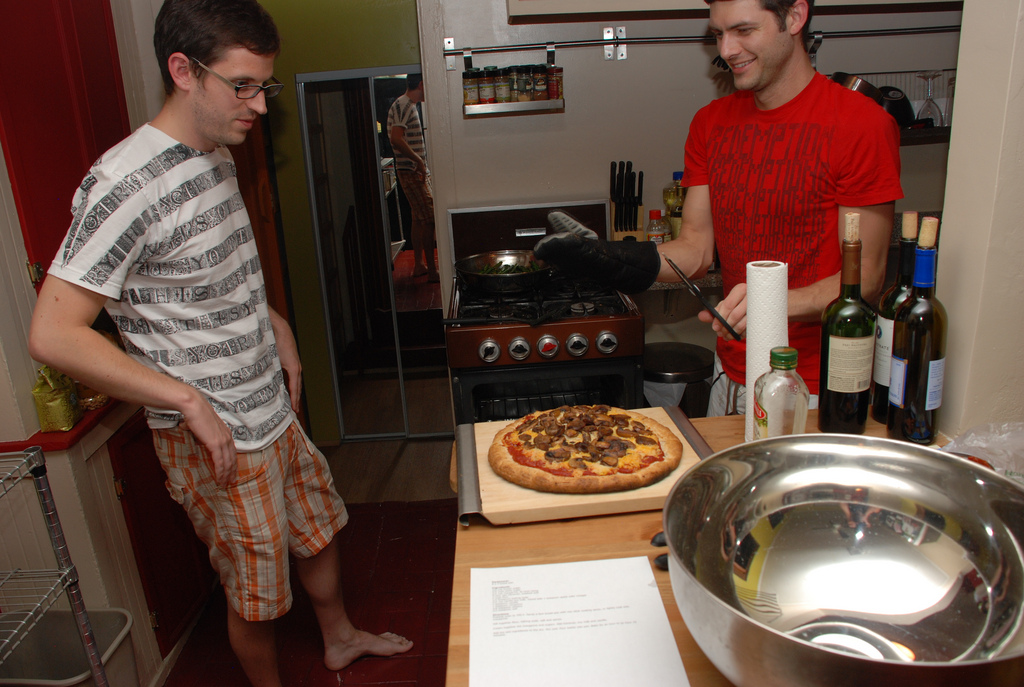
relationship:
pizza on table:
[514, 408, 674, 473] [483, 526, 618, 562]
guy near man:
[100, 44, 344, 503] [643, 15, 899, 315]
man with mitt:
[643, 15, 899, 315] [523, 200, 664, 299]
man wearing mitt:
[643, 15, 899, 315] [523, 200, 664, 299]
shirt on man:
[717, 130, 888, 232] [643, 15, 899, 315]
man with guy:
[643, 15, 899, 315] [100, 44, 344, 503]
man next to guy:
[643, 15, 899, 315] [100, 44, 344, 503]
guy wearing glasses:
[100, 44, 344, 503] [220, 69, 298, 108]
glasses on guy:
[220, 69, 298, 108] [100, 44, 344, 503]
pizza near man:
[514, 408, 674, 473] [643, 15, 899, 315]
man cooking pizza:
[643, 15, 899, 315] [514, 408, 674, 473]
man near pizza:
[643, 15, 899, 315] [514, 408, 674, 473]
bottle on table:
[804, 222, 892, 422] [483, 526, 618, 562]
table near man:
[483, 526, 618, 562] [643, 15, 899, 315]